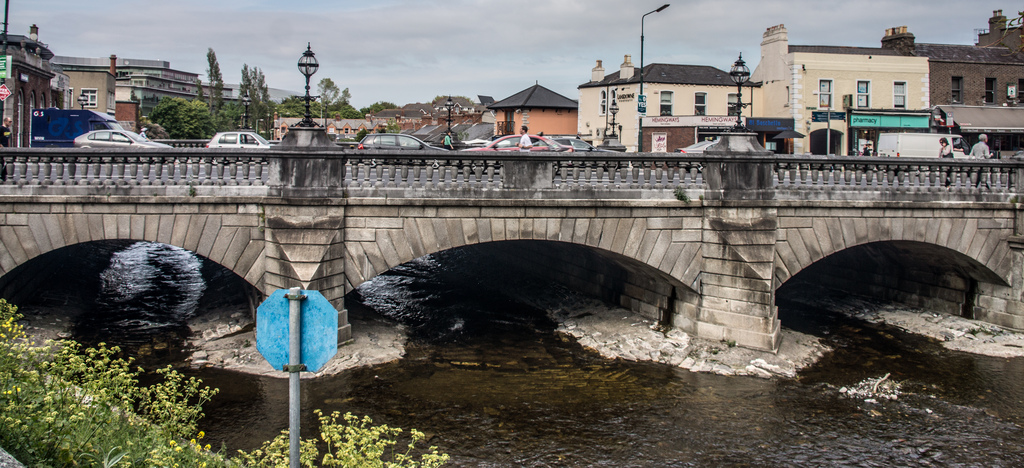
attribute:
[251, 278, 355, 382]
sign — blue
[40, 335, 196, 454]
yellow flowers — yellow 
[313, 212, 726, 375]
dark alley — Scary looking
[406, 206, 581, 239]
wall partitions — Beautifully arranged, stone 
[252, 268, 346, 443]
road sign — Blue 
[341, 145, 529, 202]
wooden poles — Short , wooden 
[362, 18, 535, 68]
clouds — Grey , heavy looking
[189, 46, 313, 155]
trees — Long , sparse leafed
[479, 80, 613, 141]
building — Maroon colored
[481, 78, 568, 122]
grey roof — grey 